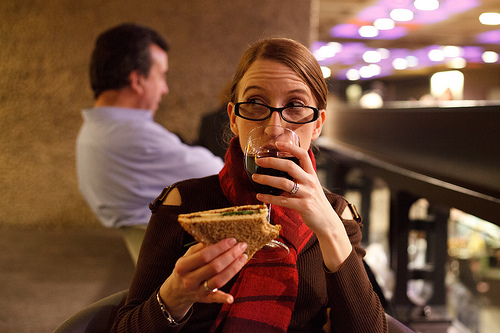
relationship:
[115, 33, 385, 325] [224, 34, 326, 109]
woman with hair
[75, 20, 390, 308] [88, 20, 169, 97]
man has hair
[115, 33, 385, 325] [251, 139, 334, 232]
woman has hand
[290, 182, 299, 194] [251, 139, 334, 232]
ring in hand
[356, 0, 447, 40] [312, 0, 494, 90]
lights are on ceiling